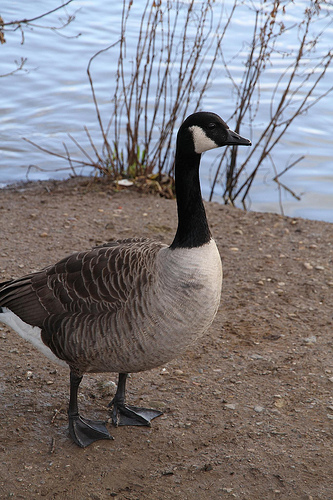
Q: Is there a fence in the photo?
A: No, there are no fences.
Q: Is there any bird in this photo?
A: Yes, there is a bird.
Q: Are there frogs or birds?
A: Yes, there is a bird.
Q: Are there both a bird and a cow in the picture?
A: No, there is a bird but no cows.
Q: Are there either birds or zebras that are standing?
A: Yes, the bird is standing.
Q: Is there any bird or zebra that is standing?
A: Yes, the bird is standing.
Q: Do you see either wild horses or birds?
A: Yes, there is a wild bird.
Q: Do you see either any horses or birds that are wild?
A: Yes, the bird is wild.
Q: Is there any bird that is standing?
A: Yes, there is a bird that is standing.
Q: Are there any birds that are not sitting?
A: Yes, there is a bird that is standing.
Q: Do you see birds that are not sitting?
A: Yes, there is a bird that is standing .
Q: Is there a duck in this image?
A: No, there are no ducks.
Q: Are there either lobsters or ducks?
A: No, there are no ducks or lobsters.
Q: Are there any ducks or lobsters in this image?
A: No, there are no ducks or lobsters.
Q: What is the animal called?
A: The animal is a bird.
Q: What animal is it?
A: The animal is a bird.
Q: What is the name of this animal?
A: This is a bird.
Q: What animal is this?
A: This is a bird.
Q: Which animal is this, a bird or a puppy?
A: This is a bird.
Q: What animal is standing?
A: The animal is a bird.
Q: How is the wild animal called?
A: The animal is a bird.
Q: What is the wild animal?
A: The animal is a bird.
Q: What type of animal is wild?
A: The animal is a bird.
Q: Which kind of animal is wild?
A: The animal is a bird.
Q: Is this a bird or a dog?
A: This is a bird.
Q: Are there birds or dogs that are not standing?
A: No, there is a bird but it is standing.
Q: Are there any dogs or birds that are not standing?
A: No, there is a bird but it is standing.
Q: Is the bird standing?
A: Yes, the bird is standing.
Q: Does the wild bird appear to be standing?
A: Yes, the bird is standing.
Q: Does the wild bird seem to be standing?
A: Yes, the bird is standing.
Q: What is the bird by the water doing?
A: The bird is standing.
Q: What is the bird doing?
A: The bird is standing.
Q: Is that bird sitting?
A: No, the bird is standing.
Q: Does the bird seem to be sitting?
A: No, the bird is standing.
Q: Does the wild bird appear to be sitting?
A: No, the bird is standing.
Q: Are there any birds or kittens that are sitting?
A: No, there is a bird but it is standing.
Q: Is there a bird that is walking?
A: No, there is a bird but it is standing.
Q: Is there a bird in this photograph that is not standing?
A: No, there is a bird but it is standing.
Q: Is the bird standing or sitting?
A: The bird is standing.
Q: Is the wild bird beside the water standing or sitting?
A: The bird is standing.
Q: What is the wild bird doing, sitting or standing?
A: The bird is standing.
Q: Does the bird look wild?
A: Yes, the bird is wild.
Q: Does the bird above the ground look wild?
A: Yes, the bird is wild.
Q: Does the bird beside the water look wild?
A: Yes, the bird is wild.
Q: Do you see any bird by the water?
A: Yes, there is a bird by the water.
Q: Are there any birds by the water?
A: Yes, there is a bird by the water.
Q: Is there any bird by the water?
A: Yes, there is a bird by the water.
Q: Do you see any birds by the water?
A: Yes, there is a bird by the water.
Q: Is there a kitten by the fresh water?
A: No, there is a bird by the water.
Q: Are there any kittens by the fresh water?
A: No, there is a bird by the water.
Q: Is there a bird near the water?
A: Yes, there is a bird near the water.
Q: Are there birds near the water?
A: Yes, there is a bird near the water.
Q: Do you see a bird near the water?
A: Yes, there is a bird near the water.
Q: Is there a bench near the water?
A: No, there is a bird near the water.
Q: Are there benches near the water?
A: No, there is a bird near the water.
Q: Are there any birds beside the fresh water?
A: Yes, there is a bird beside the water.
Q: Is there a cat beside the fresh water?
A: No, there is a bird beside the water.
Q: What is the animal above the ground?
A: The animal is a bird.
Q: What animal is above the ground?
A: The animal is a bird.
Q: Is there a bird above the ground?
A: Yes, there is a bird above the ground.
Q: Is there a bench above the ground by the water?
A: No, there is a bird above the ground.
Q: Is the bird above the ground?
A: Yes, the bird is above the ground.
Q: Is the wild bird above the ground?
A: Yes, the bird is above the ground.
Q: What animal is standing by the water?
A: The bird is standing by the water.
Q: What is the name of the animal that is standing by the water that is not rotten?
A: The animal is a bird.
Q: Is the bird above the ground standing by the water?
A: Yes, the bird is standing by the water.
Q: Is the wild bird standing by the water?
A: Yes, the bird is standing by the water.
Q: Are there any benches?
A: No, there are no benches.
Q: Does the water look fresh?
A: Yes, the water is fresh.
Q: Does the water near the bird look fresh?
A: Yes, the water is fresh.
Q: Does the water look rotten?
A: No, the water is fresh.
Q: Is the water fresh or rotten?
A: The water is fresh.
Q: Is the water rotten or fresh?
A: The water is fresh.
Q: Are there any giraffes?
A: No, there are no giraffes.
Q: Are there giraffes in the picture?
A: No, there are no giraffes.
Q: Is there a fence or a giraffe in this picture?
A: No, there are no giraffes or fences.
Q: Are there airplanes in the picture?
A: No, there are no airplanes.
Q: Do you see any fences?
A: No, there are no fences.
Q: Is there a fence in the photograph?
A: No, there are no fences.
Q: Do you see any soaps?
A: No, there are no soaps.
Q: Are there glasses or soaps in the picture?
A: No, there are no soaps or glasses.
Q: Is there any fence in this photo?
A: No, there are no fences.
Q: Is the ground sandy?
A: Yes, the ground is sandy.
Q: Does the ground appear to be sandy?
A: Yes, the ground is sandy.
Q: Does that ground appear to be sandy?
A: Yes, the ground is sandy.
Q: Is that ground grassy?
A: No, the ground is sandy.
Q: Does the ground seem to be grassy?
A: No, the ground is sandy.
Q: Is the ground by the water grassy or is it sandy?
A: The ground is sandy.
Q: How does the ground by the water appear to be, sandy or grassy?
A: The ground is sandy.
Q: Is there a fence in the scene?
A: No, there are no fences.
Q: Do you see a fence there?
A: No, there are no fences.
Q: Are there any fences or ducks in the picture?
A: No, there are no fences or ducks.